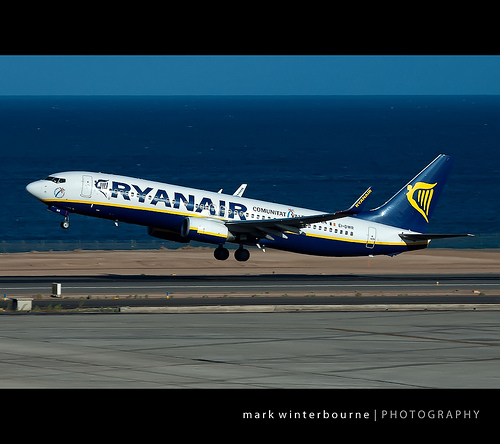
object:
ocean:
[0, 94, 500, 251]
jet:
[25, 153, 475, 262]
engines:
[179, 217, 230, 246]